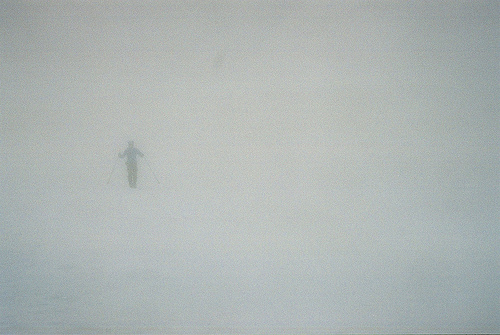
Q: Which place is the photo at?
A: It is at the field.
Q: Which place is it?
A: It is a field.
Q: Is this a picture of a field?
A: Yes, it is showing a field.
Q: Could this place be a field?
A: Yes, it is a field.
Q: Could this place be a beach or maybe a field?
A: It is a field.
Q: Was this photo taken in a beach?
A: No, the picture was taken in a field.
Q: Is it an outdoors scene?
A: Yes, it is outdoors.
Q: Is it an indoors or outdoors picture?
A: It is outdoors.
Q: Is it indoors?
A: No, it is outdoors.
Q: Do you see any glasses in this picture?
A: No, there are no glasses.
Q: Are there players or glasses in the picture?
A: No, there are no glasses or players.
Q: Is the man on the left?
A: Yes, the man is on the left of the image.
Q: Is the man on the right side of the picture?
A: No, the man is on the left of the image.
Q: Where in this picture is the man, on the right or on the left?
A: The man is on the left of the image.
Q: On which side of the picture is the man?
A: The man is on the left of the image.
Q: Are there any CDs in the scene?
A: No, there are no cds.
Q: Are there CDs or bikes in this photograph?
A: No, there are no CDs or bikes.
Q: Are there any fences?
A: No, there are no fences.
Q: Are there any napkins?
A: No, there are no napkins.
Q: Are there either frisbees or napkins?
A: No, there are no napkins or frisbees.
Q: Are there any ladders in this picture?
A: No, there are no ladders.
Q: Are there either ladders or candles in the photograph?
A: No, there are no ladders or candles.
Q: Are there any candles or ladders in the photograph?
A: No, there are no ladders or candles.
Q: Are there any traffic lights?
A: No, there are no traffic lights.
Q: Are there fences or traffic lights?
A: No, there are no traffic lights or fences.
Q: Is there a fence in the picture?
A: No, there are no fences.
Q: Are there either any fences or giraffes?
A: No, there are no fences or giraffes.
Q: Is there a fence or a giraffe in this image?
A: No, there are no fences or giraffes.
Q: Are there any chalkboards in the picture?
A: No, there are no chalkboards.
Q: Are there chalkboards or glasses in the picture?
A: No, there are no chalkboards or glasses.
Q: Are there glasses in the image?
A: No, there are no glasses.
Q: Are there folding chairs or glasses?
A: No, there are no glasses or folding chairs.